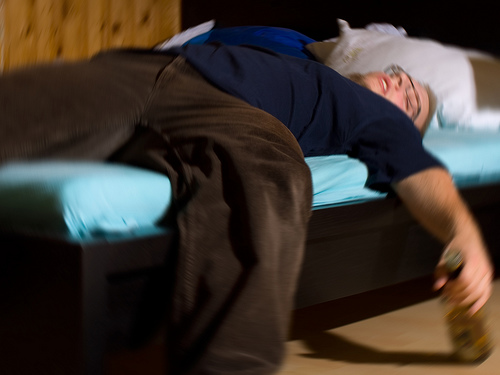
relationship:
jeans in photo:
[0, 46, 314, 374] [7, 18, 499, 364]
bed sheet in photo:
[1, 81, 500, 246] [7, 18, 499, 364]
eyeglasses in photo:
[384, 61, 425, 120] [7, 18, 499, 364]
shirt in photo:
[152, 31, 445, 184] [7, 18, 499, 364]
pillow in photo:
[305, 8, 500, 136] [7, 18, 499, 364]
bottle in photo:
[442, 251, 500, 365] [7, 18, 499, 364]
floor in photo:
[13, 263, 497, 372] [7, 18, 499, 364]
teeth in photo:
[381, 76, 389, 95] [7, 18, 499, 364]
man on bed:
[10, 29, 500, 365] [7, 18, 499, 364]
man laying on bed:
[10, 29, 500, 365] [7, 18, 499, 364]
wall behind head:
[8, 0, 186, 68] [349, 61, 442, 139]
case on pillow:
[303, 21, 500, 131] [305, 8, 500, 136]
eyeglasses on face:
[383, 63, 423, 124] [355, 59, 431, 131]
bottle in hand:
[442, 251, 500, 365] [436, 231, 498, 313]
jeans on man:
[0, 46, 314, 374] [10, 29, 500, 365]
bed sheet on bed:
[1, 81, 500, 246] [7, 18, 499, 364]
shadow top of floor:
[297, 314, 499, 370] [13, 263, 497, 372]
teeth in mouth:
[381, 76, 389, 95] [378, 70, 392, 94]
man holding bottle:
[10, 29, 500, 365] [442, 251, 500, 365]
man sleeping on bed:
[10, 29, 500, 365] [7, 18, 499, 364]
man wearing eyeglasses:
[10, 29, 500, 365] [384, 61, 425, 120]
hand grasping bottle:
[436, 231, 498, 313] [442, 251, 500, 365]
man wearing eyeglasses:
[10, 29, 500, 365] [383, 63, 423, 124]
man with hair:
[10, 29, 500, 365] [420, 82, 446, 138]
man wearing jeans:
[10, 29, 500, 365] [0, 46, 314, 374]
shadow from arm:
[297, 314, 499, 370] [389, 168, 480, 242]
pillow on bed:
[305, 8, 500, 136] [7, 18, 499, 364]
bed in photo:
[7, 18, 499, 364] [6, 8, 484, 347]